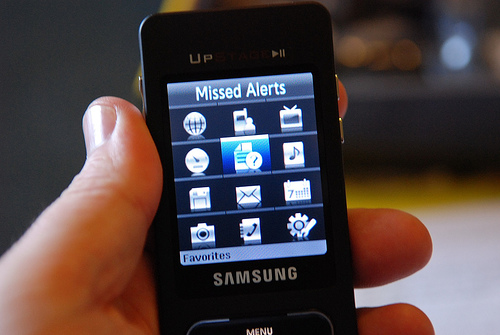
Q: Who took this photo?
A: A student.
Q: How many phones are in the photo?
A: One.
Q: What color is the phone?
A: Black.